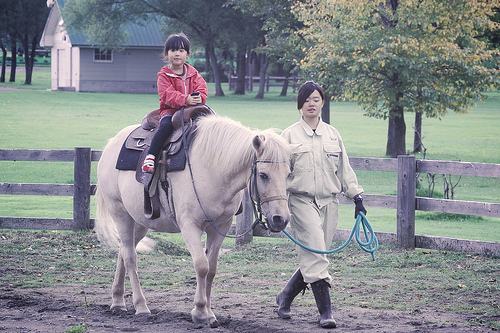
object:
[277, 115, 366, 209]
shirt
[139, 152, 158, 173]
shoes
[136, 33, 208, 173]
asian girl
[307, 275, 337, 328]
boots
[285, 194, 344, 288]
khaki pants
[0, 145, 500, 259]
fence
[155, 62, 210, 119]
jacket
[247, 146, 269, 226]
bridle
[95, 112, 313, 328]
horse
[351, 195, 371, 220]
gloves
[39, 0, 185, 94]
house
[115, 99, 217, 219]
saddle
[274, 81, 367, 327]
woman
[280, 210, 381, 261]
blue rope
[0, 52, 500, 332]
land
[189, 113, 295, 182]
hair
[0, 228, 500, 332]
dirt